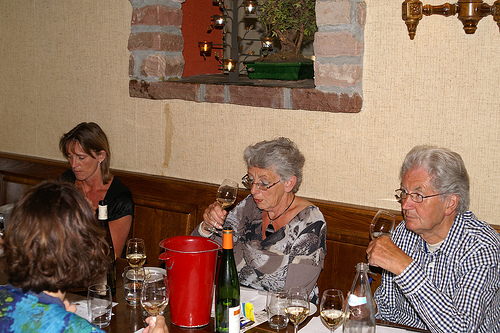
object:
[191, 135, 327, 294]
woman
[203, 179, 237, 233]
wine glass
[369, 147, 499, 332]
man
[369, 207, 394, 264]
wine glass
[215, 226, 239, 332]
bottle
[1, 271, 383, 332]
table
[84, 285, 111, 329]
glass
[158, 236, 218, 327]
bucket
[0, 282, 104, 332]
woman's shirt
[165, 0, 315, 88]
brick hole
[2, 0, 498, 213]
wall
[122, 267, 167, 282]
plate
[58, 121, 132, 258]
woman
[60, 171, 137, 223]
black shirt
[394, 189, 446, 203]
glasses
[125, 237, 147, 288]
glass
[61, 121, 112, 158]
woman's hair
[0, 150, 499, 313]
bench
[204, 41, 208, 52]
candle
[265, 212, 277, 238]
necklace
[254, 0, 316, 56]
plant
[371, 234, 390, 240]
wine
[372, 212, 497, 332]
man's shirt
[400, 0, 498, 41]
light fixture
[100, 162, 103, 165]
earrings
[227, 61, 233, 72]
candles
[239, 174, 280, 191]
glasses